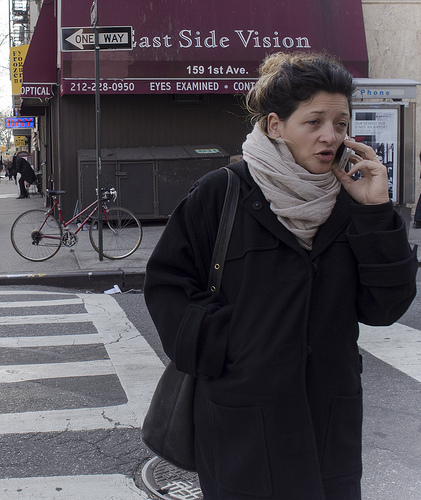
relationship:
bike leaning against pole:
[11, 185, 143, 261] [93, 21, 100, 262]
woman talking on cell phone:
[141, 52, 413, 499] [337, 142, 350, 172]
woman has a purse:
[141, 52, 413, 499] [141, 167, 241, 474]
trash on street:
[101, 284, 122, 295] [0, 284, 420, 499]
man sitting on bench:
[6, 156, 32, 197] [22, 174, 44, 199]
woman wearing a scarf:
[141, 52, 413, 499] [242, 122, 351, 249]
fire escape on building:
[11, 0, 32, 52] [30, 0, 419, 223]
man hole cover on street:
[145, 453, 203, 499] [0, 284, 420, 499]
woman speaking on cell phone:
[141, 52, 413, 499] [337, 142, 350, 172]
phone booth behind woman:
[352, 77, 420, 208] [141, 52, 413, 499]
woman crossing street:
[141, 52, 413, 499] [0, 284, 420, 499]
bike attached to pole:
[11, 185, 143, 261] [93, 21, 100, 262]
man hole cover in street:
[145, 453, 203, 499] [0, 284, 420, 499]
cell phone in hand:
[337, 142, 350, 172] [330, 138, 388, 204]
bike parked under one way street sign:
[11, 185, 143, 261] [60, 26, 132, 53]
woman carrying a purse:
[141, 52, 413, 499] [141, 167, 241, 474]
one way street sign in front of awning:
[60, 26, 132, 53] [59, 3, 368, 94]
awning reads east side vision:
[59, 3, 368, 94] [130, 26, 311, 53]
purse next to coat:
[141, 167, 241, 474] [145, 157, 414, 499]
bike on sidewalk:
[11, 185, 143, 261] [0, 168, 166, 275]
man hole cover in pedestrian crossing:
[145, 453, 203, 499] [1, 287, 182, 499]